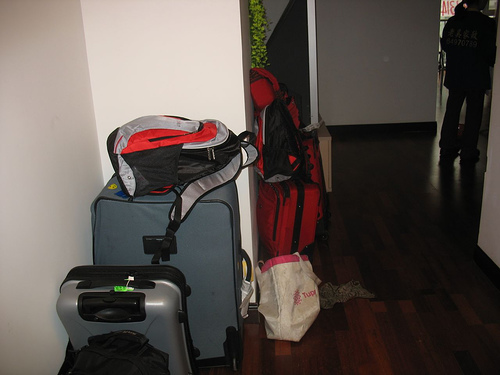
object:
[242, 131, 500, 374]
floor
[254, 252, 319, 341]
bag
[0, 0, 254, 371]
wall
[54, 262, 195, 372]
suitcase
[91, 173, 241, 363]
suitcase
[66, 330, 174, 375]
bag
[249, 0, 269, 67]
green decoration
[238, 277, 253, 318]
white tag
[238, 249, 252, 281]
handle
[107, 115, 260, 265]
backpack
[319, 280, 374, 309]
brown scarf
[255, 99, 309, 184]
backpack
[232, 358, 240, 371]
wheel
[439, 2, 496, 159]
person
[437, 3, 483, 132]
doorway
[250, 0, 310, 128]
door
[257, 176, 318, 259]
luggage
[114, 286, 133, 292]
tag